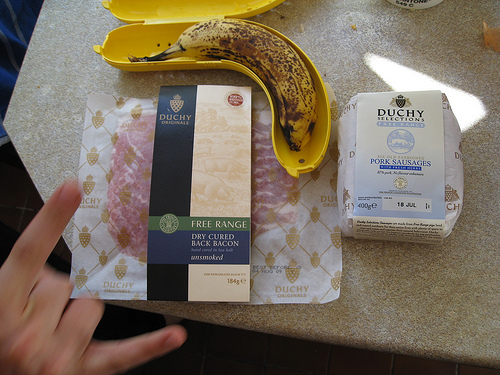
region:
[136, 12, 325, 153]
The banana is in a banana holder.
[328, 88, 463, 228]
A pack of pork sausages on the counter top.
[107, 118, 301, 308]
A pack of bacon is on the countertop.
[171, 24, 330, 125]
The banana is very ripe.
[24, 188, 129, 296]
a person finger on the countertop.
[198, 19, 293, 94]
The banana has black marking on the peeling.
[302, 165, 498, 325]
The countertop is beige.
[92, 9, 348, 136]
The banana case is shaped like a banana.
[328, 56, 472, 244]
The packaging of the sausage is white.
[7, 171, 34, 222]
The floor is made of tile.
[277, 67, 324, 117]
the banana has brown spots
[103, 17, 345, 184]
the banana is in a case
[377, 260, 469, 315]
the table is gray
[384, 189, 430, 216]
the exp date is on the package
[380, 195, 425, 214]
the exp date is black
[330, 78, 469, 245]
the package is small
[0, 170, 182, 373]
the hand is small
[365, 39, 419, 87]
the light is on the table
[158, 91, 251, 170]
the package is black and tan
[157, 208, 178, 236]
the logo is round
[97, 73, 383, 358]
picture of bacon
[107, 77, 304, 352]
the bacon has packing on it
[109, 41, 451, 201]
a banana is yellow and brown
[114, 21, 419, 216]
the banana is in a banana container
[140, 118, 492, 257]
a package of pork sausages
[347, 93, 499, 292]
the sausages are made by duchy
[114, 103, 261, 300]
the bacon is made by duchy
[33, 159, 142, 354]
a hand is next to the bacon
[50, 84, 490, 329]
the food is on the table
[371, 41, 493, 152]
the sun light on the table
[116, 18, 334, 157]
The banana is ripe.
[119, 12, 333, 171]
The banana has spots.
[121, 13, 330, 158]
Spots on banana are brown.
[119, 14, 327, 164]
The banana is unpeeled.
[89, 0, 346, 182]
The banana is crescent-shaped.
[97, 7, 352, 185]
The banana is sickle-shaped.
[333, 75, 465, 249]
Unopened package of pork sausages.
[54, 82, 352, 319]
Unopened package of back bacon.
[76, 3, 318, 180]
Banana container has holes.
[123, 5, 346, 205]
The banana is fruit.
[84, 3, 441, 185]
a banana in a holder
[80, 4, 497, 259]
banana in banana holder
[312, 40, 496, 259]
a box of pork sausages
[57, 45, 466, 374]
a bag of dry bacon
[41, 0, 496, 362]
a table with food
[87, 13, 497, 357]
food on a table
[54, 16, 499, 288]
uneaten food on table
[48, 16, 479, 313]
food on table that has not been open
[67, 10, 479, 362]
unopen food on table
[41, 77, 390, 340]
bacon in the package